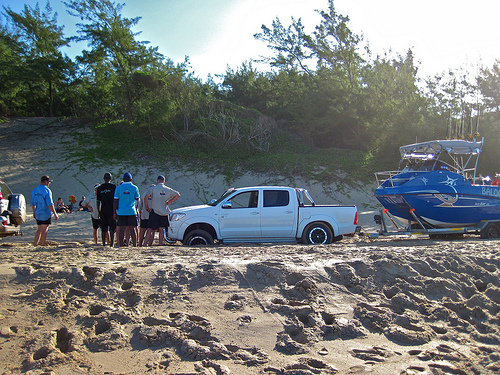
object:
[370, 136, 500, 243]
boat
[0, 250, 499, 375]
sand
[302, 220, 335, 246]
rear wheel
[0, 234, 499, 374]
ground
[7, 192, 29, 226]
spare tire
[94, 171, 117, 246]
person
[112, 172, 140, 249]
man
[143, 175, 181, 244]
people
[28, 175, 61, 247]
man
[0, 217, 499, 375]
beach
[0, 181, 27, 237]
car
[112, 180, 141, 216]
blue shirt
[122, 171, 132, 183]
baseball cap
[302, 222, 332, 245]
tire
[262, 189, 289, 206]
window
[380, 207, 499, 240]
trailer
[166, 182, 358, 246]
white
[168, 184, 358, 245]
pickup truck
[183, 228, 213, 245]
tire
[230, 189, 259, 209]
window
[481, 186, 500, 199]
letters